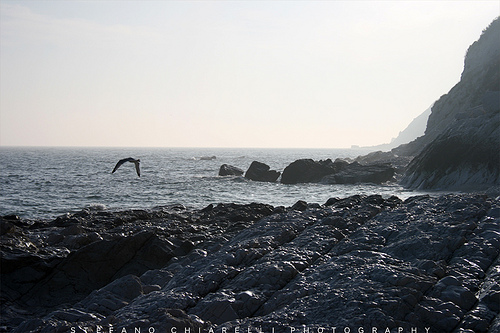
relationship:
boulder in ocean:
[217, 163, 243, 175] [1, 144, 458, 217]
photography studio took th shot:
[64, 323, 451, 332] [3, 7, 495, 317]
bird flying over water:
[108, 144, 158, 191] [28, 152, 93, 198]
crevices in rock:
[270, 256, 310, 278] [2, 190, 497, 327]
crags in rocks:
[105, 189, 322, 206] [195, 216, 432, 303]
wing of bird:
[107, 161, 124, 174] [102, 142, 162, 192]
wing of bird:
[134, 162, 143, 177] [112, 154, 141, 176]